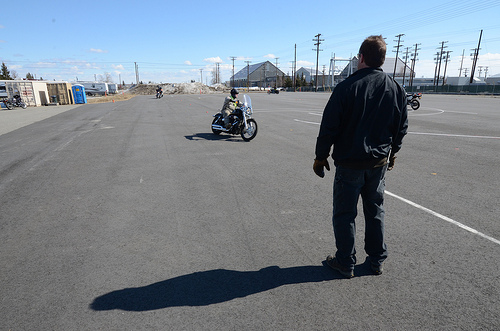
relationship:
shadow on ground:
[84, 257, 385, 314] [1, 95, 499, 331]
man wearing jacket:
[309, 32, 409, 279] [314, 67, 409, 162]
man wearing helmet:
[218, 87, 243, 128] [230, 88, 241, 97]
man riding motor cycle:
[218, 87, 243, 128] [205, 104, 261, 143]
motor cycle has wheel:
[205, 104, 261, 143] [238, 118, 259, 142]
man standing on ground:
[309, 32, 409, 279] [1, 95, 499, 331]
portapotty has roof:
[72, 83, 91, 106] [72, 83, 84, 88]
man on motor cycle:
[218, 87, 243, 128] [205, 104, 261, 143]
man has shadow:
[309, 32, 409, 279] [84, 257, 385, 314]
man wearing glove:
[309, 32, 409, 279] [313, 154, 332, 180]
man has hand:
[309, 32, 409, 279] [310, 156, 334, 178]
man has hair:
[309, 32, 409, 279] [358, 34, 386, 67]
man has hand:
[309, 32, 409, 279] [385, 150, 402, 171]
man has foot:
[309, 32, 409, 279] [323, 247, 358, 279]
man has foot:
[309, 32, 409, 279] [359, 248, 388, 274]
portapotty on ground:
[72, 83, 91, 106] [1, 95, 499, 331]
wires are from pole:
[323, 3, 499, 47] [311, 30, 324, 91]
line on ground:
[379, 187, 497, 243] [1, 95, 499, 331]